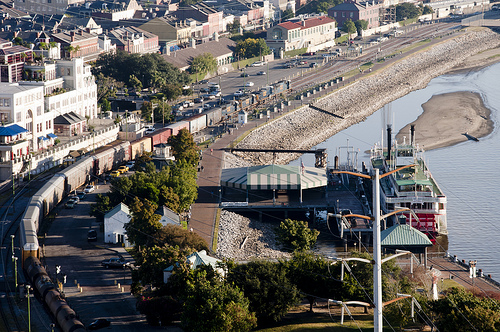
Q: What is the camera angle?
A: Pointing down.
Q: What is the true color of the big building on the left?
A: White.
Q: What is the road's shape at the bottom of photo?
A: Curved.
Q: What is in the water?
A: A boat.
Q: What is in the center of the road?
A: A train.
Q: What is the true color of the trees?
A: Green.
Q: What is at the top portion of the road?
A: A parking lot.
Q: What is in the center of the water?
A: A dirt island.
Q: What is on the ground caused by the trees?
A: Shadows.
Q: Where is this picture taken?
A: A city.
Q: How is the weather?
A: Sunny.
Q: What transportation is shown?
A: A train.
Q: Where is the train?
A: On the tracks.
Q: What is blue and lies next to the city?
A: Water.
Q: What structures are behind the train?
A: Buildings.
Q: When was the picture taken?
A: Afternoon.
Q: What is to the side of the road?
A: A large body of water.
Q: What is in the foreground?
A: Trees.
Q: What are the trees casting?
A: Shadows.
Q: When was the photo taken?
A: In the daytime.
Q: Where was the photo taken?
A: Outside during the day.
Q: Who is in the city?
A: People.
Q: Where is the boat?
A: Docked.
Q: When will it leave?
A: Soon.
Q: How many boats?
A: 1.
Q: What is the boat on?
A: Water.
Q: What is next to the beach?
A: Train.